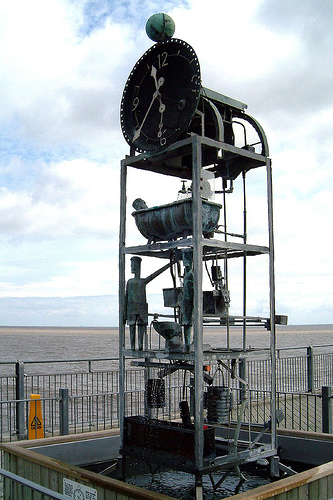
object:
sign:
[31, 416, 42, 430]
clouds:
[0, 1, 332, 291]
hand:
[151, 65, 166, 113]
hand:
[132, 76, 165, 143]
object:
[59, 387, 69, 436]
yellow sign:
[28, 394, 44, 440]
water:
[0, 324, 332, 435]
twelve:
[157, 52, 168, 70]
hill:
[0, 289, 121, 325]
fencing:
[0, 373, 117, 436]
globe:
[145, 12, 175, 43]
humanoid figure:
[123, 256, 148, 351]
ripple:
[0, 324, 333, 431]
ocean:
[1, 324, 333, 439]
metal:
[119, 159, 126, 450]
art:
[97, 12, 288, 500]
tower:
[96, 12, 297, 500]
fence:
[2, 345, 332, 437]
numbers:
[160, 129, 167, 146]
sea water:
[0, 325, 332, 435]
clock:
[120, 38, 202, 154]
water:
[98, 460, 275, 499]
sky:
[0, 0, 333, 296]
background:
[0, 282, 333, 326]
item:
[29, 394, 44, 440]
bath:
[131, 197, 223, 245]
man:
[132, 197, 148, 209]